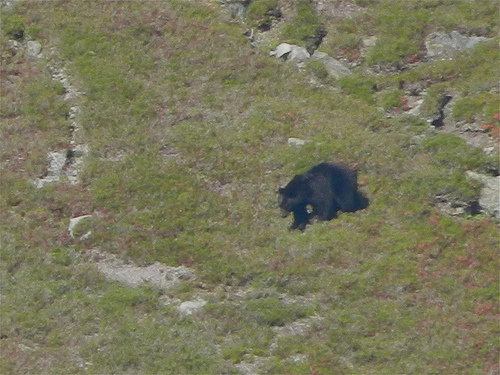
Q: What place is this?
A: It is a field.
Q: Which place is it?
A: It is a field.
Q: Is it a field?
A: Yes, it is a field.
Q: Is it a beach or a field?
A: It is a field.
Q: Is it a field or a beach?
A: It is a field.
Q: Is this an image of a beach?
A: No, the picture is showing a field.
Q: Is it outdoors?
A: Yes, it is outdoors.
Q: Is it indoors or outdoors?
A: It is outdoors.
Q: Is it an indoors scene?
A: No, it is outdoors.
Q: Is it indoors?
A: No, it is outdoors.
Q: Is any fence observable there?
A: No, there are no fences.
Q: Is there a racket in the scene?
A: No, there are no rackets.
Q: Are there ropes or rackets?
A: No, there are no rackets or ropes.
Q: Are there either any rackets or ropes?
A: No, there are no rackets or ropes.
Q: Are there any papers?
A: No, there are no papers.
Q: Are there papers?
A: No, there are no papers.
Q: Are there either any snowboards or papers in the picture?
A: No, there are no papers or snowboards.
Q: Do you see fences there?
A: No, there are no fences.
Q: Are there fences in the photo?
A: No, there are no fences.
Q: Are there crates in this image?
A: No, there are no crates.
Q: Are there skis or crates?
A: No, there are no crates or skis.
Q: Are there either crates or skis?
A: No, there are no crates or skis.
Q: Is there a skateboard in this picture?
A: No, there are no skateboards.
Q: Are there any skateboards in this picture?
A: No, there are no skateboards.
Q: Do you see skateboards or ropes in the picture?
A: No, there are no skateboards or ropes.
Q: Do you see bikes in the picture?
A: No, there are no bikes.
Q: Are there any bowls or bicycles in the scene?
A: No, there are no bicycles or bowls.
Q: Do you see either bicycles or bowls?
A: No, there are no bicycles or bowls.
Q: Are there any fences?
A: No, there are no fences.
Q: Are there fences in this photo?
A: No, there are no fences.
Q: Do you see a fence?
A: No, there are no fences.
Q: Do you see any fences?
A: No, there are no fences.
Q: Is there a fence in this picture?
A: No, there are no fences.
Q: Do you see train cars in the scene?
A: No, there are no train cars.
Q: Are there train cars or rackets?
A: No, there are no train cars or rackets.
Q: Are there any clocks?
A: No, there are no clocks.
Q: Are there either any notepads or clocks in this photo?
A: No, there are no clocks or notepads.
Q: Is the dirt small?
A: Yes, the dirt is small.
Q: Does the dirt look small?
A: Yes, the dirt is small.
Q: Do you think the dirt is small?
A: Yes, the dirt is small.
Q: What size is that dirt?
A: The dirt is small.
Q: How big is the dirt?
A: The dirt is small.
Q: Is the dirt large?
A: No, the dirt is small.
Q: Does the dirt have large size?
A: No, the dirt is small.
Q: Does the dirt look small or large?
A: The dirt is small.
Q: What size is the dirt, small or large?
A: The dirt is small.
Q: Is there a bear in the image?
A: Yes, there is a bear.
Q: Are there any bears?
A: Yes, there is a bear.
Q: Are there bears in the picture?
A: Yes, there is a bear.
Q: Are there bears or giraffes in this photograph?
A: Yes, there is a bear.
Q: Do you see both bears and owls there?
A: No, there is a bear but no owls.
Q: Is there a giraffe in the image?
A: No, there are no giraffes.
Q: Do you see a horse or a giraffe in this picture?
A: No, there are no giraffes or horses.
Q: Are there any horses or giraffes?
A: No, there are no giraffes or horses.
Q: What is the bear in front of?
A: The bear is in front of the rocks.